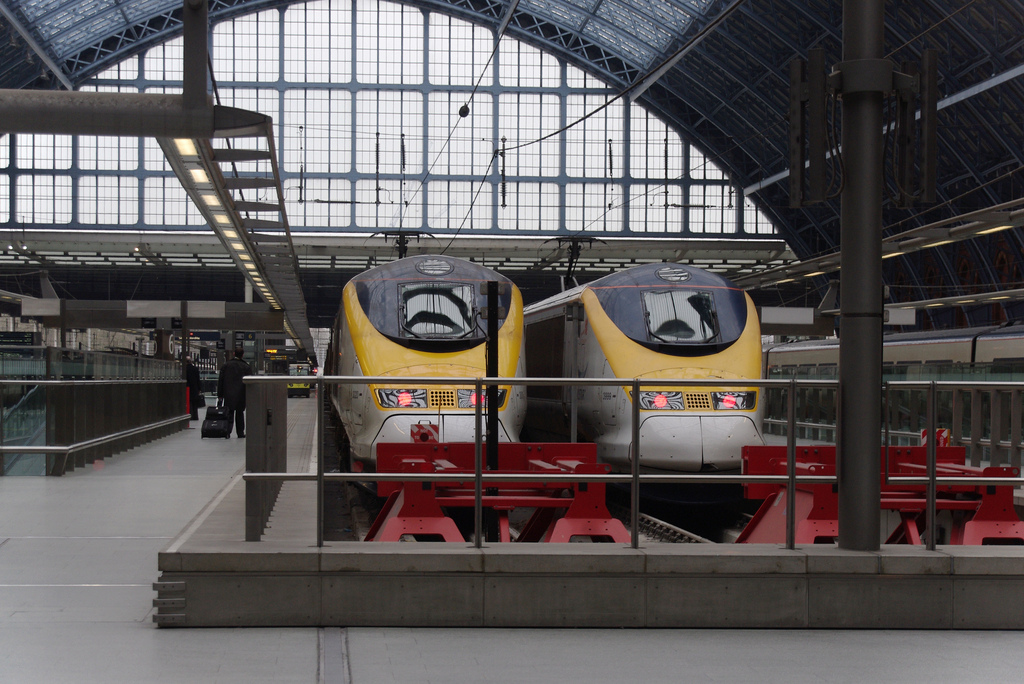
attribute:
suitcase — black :
[198, 398, 244, 428]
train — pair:
[324, 255, 533, 522]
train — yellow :
[320, 280, 535, 483]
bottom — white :
[601, 411, 772, 475]